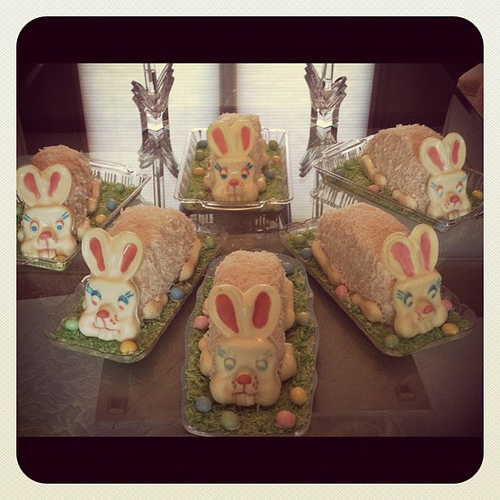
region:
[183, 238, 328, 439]
a rabbit shaped cake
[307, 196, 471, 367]
a rabbit shaped cake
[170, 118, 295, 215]
a rabbit shaped cake in a container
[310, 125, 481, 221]
a rabbit shaped cake in a container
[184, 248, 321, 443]
chocolate eggs around the cake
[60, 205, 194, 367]
chocolate eggs around the cake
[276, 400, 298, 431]
pink chocolate egg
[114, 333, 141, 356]
a yellow chocolate egg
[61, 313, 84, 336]
a green chocolate egg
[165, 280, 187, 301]
a blue chocolate egg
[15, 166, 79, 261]
the plastic face of a rabbit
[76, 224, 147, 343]
the plastic face of a rabbit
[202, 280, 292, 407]
the plastic face of a rabbit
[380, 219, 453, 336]
the plastic face of a rabbit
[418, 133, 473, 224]
the plastic face of a rabbit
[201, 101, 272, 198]
the plastic face of a rabbit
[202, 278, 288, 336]
the ears of a plastic rabbit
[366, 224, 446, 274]
the ears of a plastic rabbit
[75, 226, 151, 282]
the ears of a plastic rabbit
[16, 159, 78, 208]
the ears of a plastic rabbit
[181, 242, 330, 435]
A cake shaped like a bunny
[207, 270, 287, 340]
The bunny ears on the cake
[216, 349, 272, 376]
The bunny eye on the cake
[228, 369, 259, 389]
The nose on the cake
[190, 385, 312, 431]
The Easter eggs around the cake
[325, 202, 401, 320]
The loaf part of the cake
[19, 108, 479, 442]
Six bunny cakes on the table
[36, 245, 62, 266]
The teeth on the bunny cake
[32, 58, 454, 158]
The table is made of glass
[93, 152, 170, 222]
The clear tray the cake is in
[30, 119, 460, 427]
BUNNY CAKES ON DISPLAY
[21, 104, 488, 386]
THESE CAKES WERE MADE FOR EASTER SEASON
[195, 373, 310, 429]
EGGS USED AS GARNISH AROUND BUNNY CAKE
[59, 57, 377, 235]
BLINDS OVER A WINDOW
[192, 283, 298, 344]
INSIDE OF BUNNY'S EARS ARE BRIGHT PINK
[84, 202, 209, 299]
COCONUT HAS BEEN SPRINKLED ON FROSTING OF CAKE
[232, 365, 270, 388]
NOSE ON BUNNY'S FACE MATCHES THE COLOR OF INSIDE OF EARS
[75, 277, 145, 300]
BUNNY FACE HAS BLUE EYELASHES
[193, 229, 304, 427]
GLASS PANS ARE LINED WITH EASTER GRASS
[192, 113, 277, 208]
bunny cake on tray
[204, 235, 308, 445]
bunny cake on tray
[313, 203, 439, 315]
bunny cake on tray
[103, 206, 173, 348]
bunny cake on tray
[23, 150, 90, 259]
bunny cake on tray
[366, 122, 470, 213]
bunny cake on tray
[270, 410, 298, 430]
egg on the tray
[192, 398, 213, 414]
egg on the tray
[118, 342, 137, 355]
egg on the tray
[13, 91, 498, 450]
a group of bunnies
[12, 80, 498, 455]
some dessert items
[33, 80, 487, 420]
a scene insides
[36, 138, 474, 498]
a table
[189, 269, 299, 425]
a bunnies' face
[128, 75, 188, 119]
a plastic object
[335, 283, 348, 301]
the piece of candy is pink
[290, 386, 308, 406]
the piece of candy is yellow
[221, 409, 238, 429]
the piece of candy is green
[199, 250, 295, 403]
the dessert in the shape of a rabbit